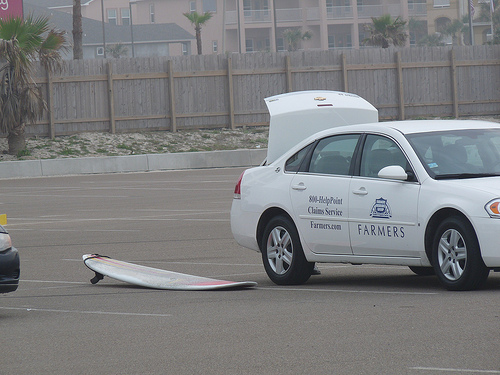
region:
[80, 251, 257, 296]
a surfboard on the concrete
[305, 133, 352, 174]
window on a car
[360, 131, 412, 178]
window on a car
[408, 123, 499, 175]
window on the front of a car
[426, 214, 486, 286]
front wheel of a car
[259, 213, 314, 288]
wheel on a car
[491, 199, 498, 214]
blinker on a car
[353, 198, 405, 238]
logo for farmers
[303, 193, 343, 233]
blue text on a white car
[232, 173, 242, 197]
red tail light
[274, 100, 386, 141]
trunk is opened on car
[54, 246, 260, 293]
surfboard on the ground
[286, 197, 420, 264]
name on side of car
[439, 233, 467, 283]
wire wheels on the tires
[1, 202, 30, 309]
back of car parked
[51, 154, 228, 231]
white lines in the street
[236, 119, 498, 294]
car is white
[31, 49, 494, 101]
long wooden fence surrounds area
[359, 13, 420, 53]
palm tree behind the fence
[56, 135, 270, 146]
stones in front of fence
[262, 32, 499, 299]
this is a car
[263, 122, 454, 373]
the car is white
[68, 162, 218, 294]
this is a surfboard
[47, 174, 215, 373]
the board is plastic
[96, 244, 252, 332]
the board is white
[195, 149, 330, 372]
this is a wheel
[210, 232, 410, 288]
the wheel is silver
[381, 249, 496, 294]
this is a tire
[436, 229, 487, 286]
the tire is black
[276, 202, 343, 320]
the tire is rubber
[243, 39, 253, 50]
a window of a building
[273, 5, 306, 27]
a white balcony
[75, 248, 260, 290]
a long surfboard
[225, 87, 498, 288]
part of a white car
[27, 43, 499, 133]
a long wooden fence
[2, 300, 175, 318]
a long white line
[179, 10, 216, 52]
part of a tall tree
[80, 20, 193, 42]
part of a roof of a building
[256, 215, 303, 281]
a large black car tire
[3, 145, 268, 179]
a small concrete wall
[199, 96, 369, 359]
this is a car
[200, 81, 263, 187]
this is a trunk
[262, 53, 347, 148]
the trunk is open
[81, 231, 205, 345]
this is a surfboard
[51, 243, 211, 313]
the board is made of plastic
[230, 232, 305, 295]
this is a wheel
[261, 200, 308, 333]
the wheel is silver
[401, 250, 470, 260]
the tire is black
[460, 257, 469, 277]
the tire is rubber